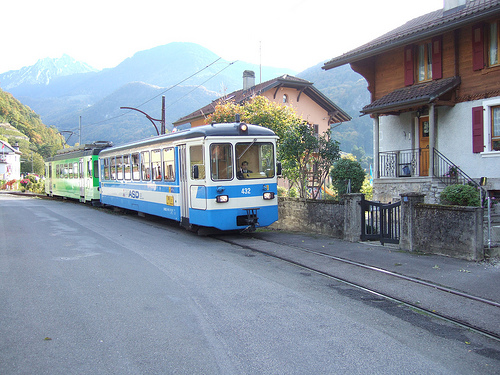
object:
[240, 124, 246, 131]
light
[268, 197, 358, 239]
wall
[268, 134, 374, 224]
yard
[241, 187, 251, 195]
numbers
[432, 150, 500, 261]
steps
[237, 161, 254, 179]
conductor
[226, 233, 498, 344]
tracks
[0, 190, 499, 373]
street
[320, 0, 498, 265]
building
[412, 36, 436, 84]
window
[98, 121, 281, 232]
train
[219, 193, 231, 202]
lights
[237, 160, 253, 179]
person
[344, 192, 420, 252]
gate